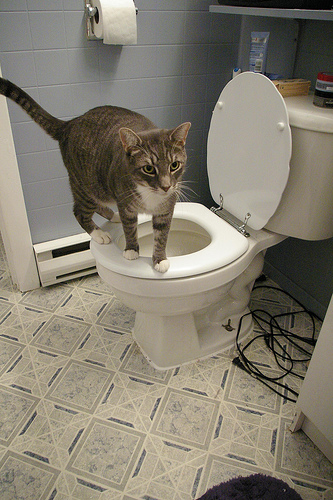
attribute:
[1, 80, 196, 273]
cat — gray, tabby, grey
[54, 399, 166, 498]
tile — blue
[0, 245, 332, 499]
floor — tiled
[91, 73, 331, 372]
toilet — white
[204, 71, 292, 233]
lid — white, up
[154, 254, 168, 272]
paw — white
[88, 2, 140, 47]
toilet paper — rolled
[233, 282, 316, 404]
cord — black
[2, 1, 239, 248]
wall — tiled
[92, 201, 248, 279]
seat — white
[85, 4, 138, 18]
holder — silver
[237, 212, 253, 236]
hinge — metal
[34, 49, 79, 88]
tile — square